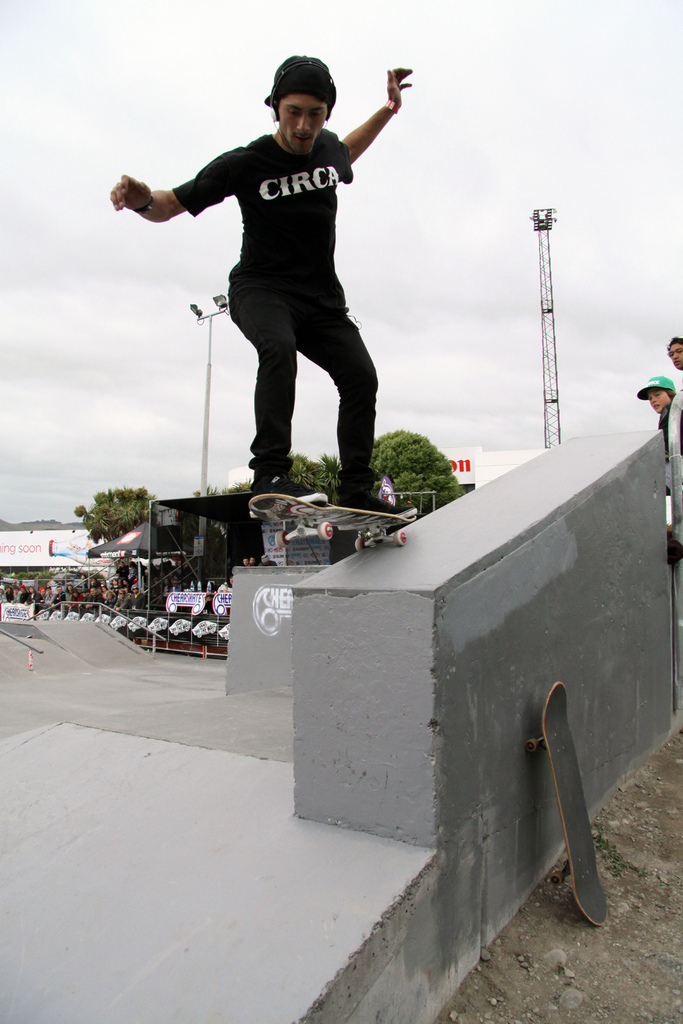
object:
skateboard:
[526, 679, 608, 931]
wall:
[293, 429, 673, 1021]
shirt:
[172, 131, 353, 315]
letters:
[252, 583, 294, 637]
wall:
[226, 572, 295, 692]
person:
[637, 377, 676, 498]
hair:
[667, 331, 682, 374]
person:
[109, 50, 416, 524]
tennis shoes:
[251, 473, 417, 519]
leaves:
[89, 493, 121, 543]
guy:
[108, 54, 411, 523]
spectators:
[90, 572, 128, 588]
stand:
[64, 586, 147, 613]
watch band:
[133, 195, 155, 214]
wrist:
[134, 191, 157, 219]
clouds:
[0, 0, 183, 175]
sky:
[0, 0, 682, 282]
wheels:
[275, 520, 408, 552]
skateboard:
[248, 492, 416, 549]